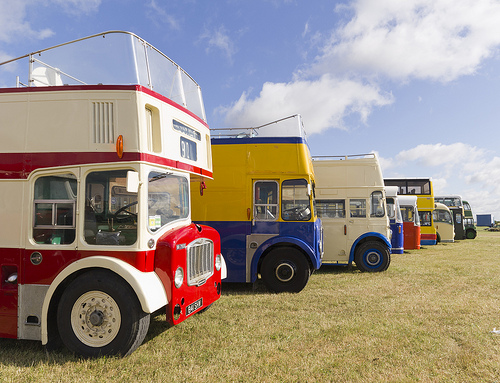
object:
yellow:
[181, 142, 318, 221]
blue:
[189, 220, 323, 282]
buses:
[0, 29, 225, 360]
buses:
[309, 151, 392, 274]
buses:
[382, 184, 404, 256]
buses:
[404, 194, 421, 250]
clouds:
[378, 140, 498, 207]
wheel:
[53, 265, 146, 360]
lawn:
[2, 224, 494, 381]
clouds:
[0, 0, 57, 47]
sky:
[0, 0, 498, 220]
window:
[82, 169, 143, 251]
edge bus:
[272, 190, 292, 230]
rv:
[204, 117, 320, 290]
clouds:
[139, 4, 180, 30]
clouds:
[53, 1, 100, 18]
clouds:
[192, 20, 237, 69]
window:
[30, 175, 78, 246]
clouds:
[332, 6, 496, 76]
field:
[0, 217, 500, 382]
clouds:
[238, 72, 360, 143]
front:
[208, 139, 321, 292]